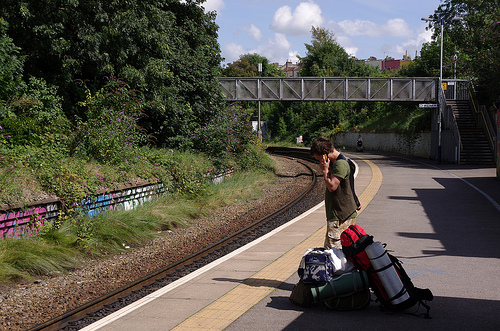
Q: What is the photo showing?
A: It is showing a walkway.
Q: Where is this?
A: This is at the walkway.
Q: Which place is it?
A: It is a walkway.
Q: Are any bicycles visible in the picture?
A: No, there are no bicycles.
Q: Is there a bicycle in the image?
A: No, there are no bicycles.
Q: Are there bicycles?
A: No, there are no bicycles.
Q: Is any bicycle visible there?
A: No, there are no bicycles.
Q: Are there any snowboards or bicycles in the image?
A: No, there are no bicycles or snowboards.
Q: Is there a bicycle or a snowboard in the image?
A: No, there are no bicycles or snowboards.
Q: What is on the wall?
A: The graffiti is on the wall.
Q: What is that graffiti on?
A: The graffiti is on the wall.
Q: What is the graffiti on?
A: The graffiti is on the wall.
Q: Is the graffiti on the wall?
A: Yes, the graffiti is on the wall.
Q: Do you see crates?
A: No, there are no crates.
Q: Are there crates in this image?
A: No, there are no crates.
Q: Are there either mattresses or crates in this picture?
A: No, there are no crates or mattresses.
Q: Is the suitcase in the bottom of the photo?
A: Yes, the suitcase is in the bottom of the image.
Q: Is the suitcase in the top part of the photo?
A: No, the suitcase is in the bottom of the image.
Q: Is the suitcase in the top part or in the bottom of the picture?
A: The suitcase is in the bottom of the image.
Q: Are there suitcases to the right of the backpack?
A: No, the suitcase is to the left of the backpack.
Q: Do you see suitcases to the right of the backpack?
A: No, the suitcase is to the left of the backpack.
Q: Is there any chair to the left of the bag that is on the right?
A: No, there is a suitcase to the left of the backpack.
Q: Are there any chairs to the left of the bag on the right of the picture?
A: No, there is a suitcase to the left of the backpack.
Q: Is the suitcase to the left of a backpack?
A: Yes, the suitcase is to the left of a backpack.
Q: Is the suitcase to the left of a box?
A: No, the suitcase is to the left of a backpack.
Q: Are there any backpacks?
A: Yes, there is a backpack.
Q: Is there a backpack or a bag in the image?
A: Yes, there is a backpack.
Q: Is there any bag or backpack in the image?
A: Yes, there is a backpack.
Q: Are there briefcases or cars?
A: No, there are no cars or briefcases.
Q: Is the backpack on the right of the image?
A: Yes, the backpack is on the right of the image.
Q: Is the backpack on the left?
A: No, the backpack is on the right of the image.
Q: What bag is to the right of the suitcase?
A: The bag is a backpack.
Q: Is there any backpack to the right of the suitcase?
A: Yes, there is a backpack to the right of the suitcase.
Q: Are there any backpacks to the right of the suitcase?
A: Yes, there is a backpack to the right of the suitcase.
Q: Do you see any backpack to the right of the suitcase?
A: Yes, there is a backpack to the right of the suitcase.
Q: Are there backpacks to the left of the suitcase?
A: No, the backpack is to the right of the suitcase.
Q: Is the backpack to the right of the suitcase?
A: Yes, the backpack is to the right of the suitcase.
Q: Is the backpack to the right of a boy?
A: No, the backpack is to the right of the suitcase.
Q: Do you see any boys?
A: No, there are no boys.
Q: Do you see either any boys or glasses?
A: No, there are no boys or glasses.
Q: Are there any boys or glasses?
A: No, there are no boys or glasses.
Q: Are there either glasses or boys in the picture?
A: No, there are no boys or glasses.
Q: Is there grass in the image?
A: Yes, there is grass.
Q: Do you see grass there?
A: Yes, there is grass.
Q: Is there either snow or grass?
A: Yes, there is grass.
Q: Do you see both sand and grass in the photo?
A: No, there is grass but no sand.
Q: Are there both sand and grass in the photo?
A: No, there is grass but no sand.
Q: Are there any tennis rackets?
A: No, there are no tennis rackets.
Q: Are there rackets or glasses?
A: No, there are no rackets or glasses.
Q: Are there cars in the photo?
A: No, there are no cars.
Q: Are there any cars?
A: No, there are no cars.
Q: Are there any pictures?
A: No, there are no pictures.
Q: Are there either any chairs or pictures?
A: No, there are no pictures or chairs.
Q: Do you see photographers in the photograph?
A: No, there are no photographers.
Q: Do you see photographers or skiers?
A: No, there are no photographers or skiers.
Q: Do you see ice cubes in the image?
A: No, there are no ice cubes.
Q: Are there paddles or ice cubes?
A: No, there are no ice cubes or paddles.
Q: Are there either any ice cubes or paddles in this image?
A: No, there are no ice cubes or paddles.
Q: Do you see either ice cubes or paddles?
A: No, there are no ice cubes or paddles.